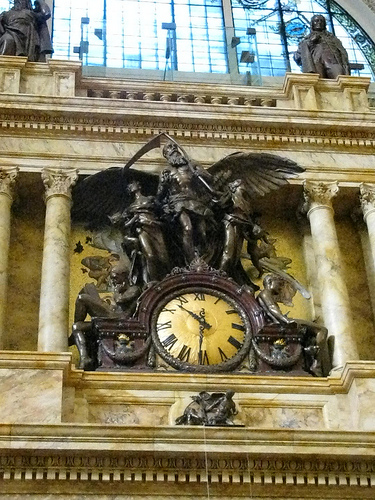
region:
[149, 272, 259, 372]
this is a clock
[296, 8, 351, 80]
this is a person statue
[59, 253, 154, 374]
this is a person statue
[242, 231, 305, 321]
this is a person statue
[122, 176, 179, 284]
this is a person statue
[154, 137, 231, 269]
this is a person statue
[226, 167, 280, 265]
this is a person statue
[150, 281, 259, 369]
Black and yellow clock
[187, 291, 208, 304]
Small roman numberal on a clock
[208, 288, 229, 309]
Small roman numberal on a clock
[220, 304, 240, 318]
Small roman numberal on a clock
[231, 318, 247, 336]
Small roman numberal on a clock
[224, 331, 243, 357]
Small roman numberal on a clock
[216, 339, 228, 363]
Small roman numberal on a clock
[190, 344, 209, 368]
Small roman numberal on a clock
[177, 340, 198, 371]
Small roman numberal on a clock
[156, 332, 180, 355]
Small roman numberal on a clock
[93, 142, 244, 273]
the statues are bronze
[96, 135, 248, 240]
the statues are of people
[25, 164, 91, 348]
this is a stone pillar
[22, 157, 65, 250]
the pillar is old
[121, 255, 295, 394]
this is a clock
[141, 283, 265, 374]
the clock is yellow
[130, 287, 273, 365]
the clock has hands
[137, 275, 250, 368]
the clock hands are black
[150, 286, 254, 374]
gold clock face with brown numerals and hands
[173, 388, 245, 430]
small brown metal statue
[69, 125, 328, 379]
large brown metal statue behind clock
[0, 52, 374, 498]
beige and brown marble building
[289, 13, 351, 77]
brown statue that is looking down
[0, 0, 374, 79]
stained glass window behind statues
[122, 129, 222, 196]
sickle in hands of statue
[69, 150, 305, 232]
wings on back of brown statue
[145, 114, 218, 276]
a statue of a man with a tool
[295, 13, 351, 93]
the statue of a guy on a ledge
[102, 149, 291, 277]
a cluster of sculptures together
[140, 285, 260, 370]
an old world style clock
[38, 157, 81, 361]
a tall marble column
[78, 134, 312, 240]
a statue of an angel with a scythe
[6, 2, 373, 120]
statues in a cathedral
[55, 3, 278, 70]
blue stained glass panels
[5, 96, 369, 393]
sculpted clock statues and structures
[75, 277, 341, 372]
an old bronze roman numeral clock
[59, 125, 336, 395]
This is a big wall clock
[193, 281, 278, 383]
a section of a wall clock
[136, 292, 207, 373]
a section of a wall clock